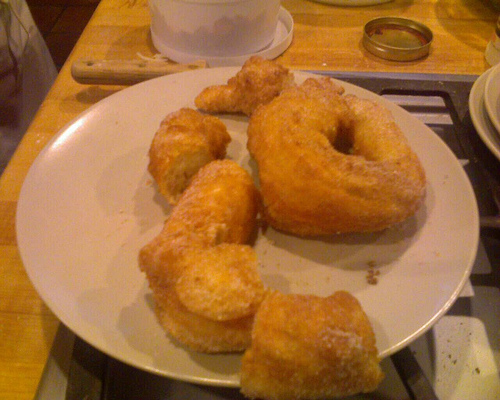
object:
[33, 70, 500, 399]
placemat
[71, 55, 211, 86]
handle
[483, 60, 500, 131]
plate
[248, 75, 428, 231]
doughnut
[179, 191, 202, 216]
sugar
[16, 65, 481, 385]
plate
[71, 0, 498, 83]
counter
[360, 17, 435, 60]
lid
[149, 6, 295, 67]
lid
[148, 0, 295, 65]
container